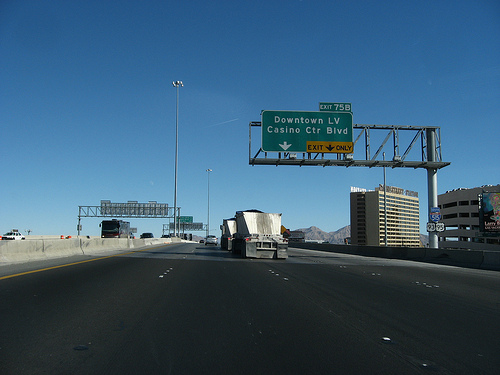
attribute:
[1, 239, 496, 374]
highway — dark gray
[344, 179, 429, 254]
building — several levels, tall 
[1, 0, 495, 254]
sky — blue, white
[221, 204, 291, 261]
truck — semi  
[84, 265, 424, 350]
road — paved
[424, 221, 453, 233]
signs — black , white 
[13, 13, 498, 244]
sky — clear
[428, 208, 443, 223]
street sign — blue, white, red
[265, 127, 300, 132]
text — white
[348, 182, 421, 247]
building — distant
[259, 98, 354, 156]
sign — green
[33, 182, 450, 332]
street — black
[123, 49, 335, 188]
light — tall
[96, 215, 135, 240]
bus — large, tour bus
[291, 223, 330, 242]
mountain — grey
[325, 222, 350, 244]
mountain — grey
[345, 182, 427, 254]
larger building — large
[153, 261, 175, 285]
lines — white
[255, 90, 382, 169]
sign — green , white 